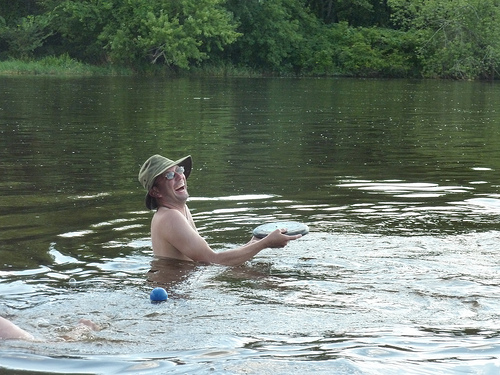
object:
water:
[0, 74, 500, 375]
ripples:
[0, 165, 500, 375]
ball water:
[0, 0, 500, 375]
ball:
[149, 288, 168, 301]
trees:
[0, 0, 500, 82]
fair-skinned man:
[139, 153, 304, 269]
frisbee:
[252, 221, 309, 240]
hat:
[138, 154, 193, 210]